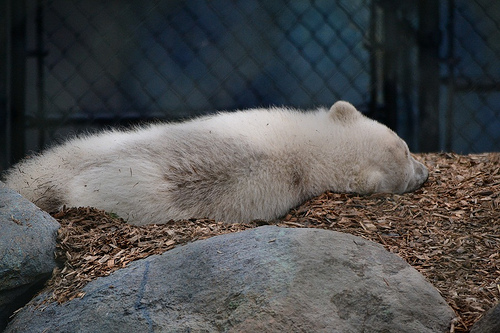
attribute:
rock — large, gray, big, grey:
[1, 219, 471, 333]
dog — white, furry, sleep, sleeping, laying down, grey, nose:
[5, 89, 433, 233]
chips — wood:
[365, 195, 500, 268]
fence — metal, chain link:
[1, 2, 496, 101]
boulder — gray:
[0, 178, 71, 312]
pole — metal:
[15, 1, 48, 153]